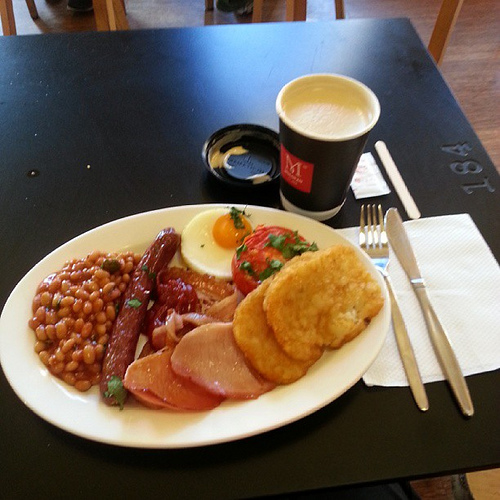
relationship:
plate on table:
[19, 152, 409, 464] [0, 11, 499, 498]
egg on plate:
[180, 206, 256, 278] [19, 152, 409, 464]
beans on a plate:
[27, 248, 144, 395] [34, 216, 351, 453]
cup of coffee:
[271, 68, 380, 223] [284, 81, 369, 137]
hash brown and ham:
[257, 242, 384, 365] [168, 318, 272, 398]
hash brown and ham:
[234, 281, 308, 384] [125, 352, 222, 410]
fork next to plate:
[355, 199, 431, 413] [19, 152, 409, 464]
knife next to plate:
[385, 201, 474, 411] [19, 152, 409, 464]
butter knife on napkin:
[383, 204, 474, 418] [329, 207, 499, 389]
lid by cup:
[201, 119, 283, 191] [271, 68, 380, 223]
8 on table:
[450, 156, 482, 176] [7, 33, 498, 467]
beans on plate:
[27, 248, 144, 395] [19, 152, 409, 464]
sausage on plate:
[100, 227, 177, 406] [19, 152, 409, 464]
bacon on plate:
[149, 263, 235, 321] [19, 152, 409, 464]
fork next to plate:
[351, 203, 433, 422] [19, 152, 409, 464]